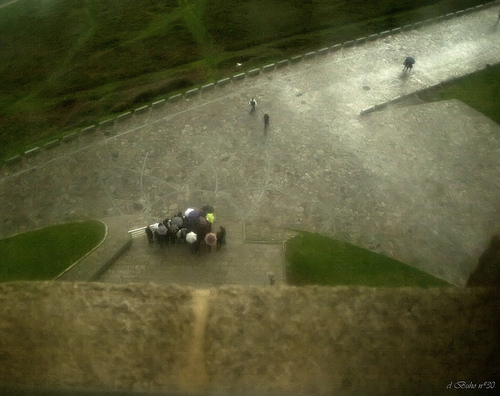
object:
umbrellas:
[162, 218, 172, 229]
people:
[218, 224, 227, 244]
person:
[199, 229, 205, 245]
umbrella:
[185, 208, 195, 218]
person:
[182, 219, 189, 228]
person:
[263, 113, 270, 126]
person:
[249, 96, 258, 111]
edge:
[0, 278, 500, 396]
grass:
[0, 0, 496, 160]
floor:
[0, 0, 500, 285]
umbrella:
[205, 212, 215, 224]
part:
[205, 212, 216, 224]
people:
[144, 224, 155, 244]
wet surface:
[82, 132, 284, 284]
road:
[0, 0, 500, 286]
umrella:
[185, 231, 198, 245]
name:
[445, 378, 498, 390]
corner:
[430, 352, 499, 394]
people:
[405, 63, 413, 71]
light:
[418, 31, 479, 69]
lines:
[139, 158, 146, 199]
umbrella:
[188, 210, 199, 219]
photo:
[0, 0, 500, 396]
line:
[102, 99, 211, 143]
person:
[205, 218, 212, 233]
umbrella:
[157, 225, 169, 236]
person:
[155, 234, 166, 250]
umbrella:
[201, 203, 215, 214]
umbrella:
[405, 56, 416, 64]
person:
[402, 64, 409, 71]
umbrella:
[204, 232, 218, 246]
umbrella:
[168, 224, 178, 234]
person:
[175, 229, 182, 245]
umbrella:
[179, 227, 187, 238]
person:
[171, 214, 177, 221]